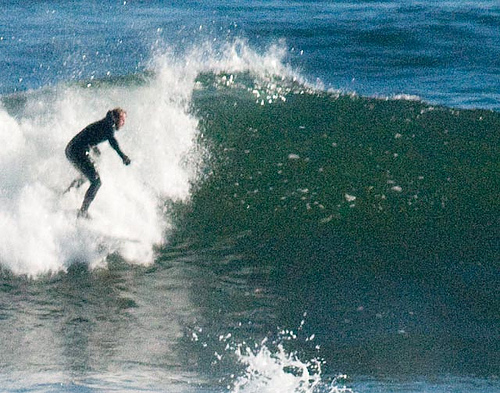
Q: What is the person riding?
A: A surfboard.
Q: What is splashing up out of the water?
A: Foam.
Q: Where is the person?
A: On the sea.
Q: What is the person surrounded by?
A: Foam splashing up out of the water.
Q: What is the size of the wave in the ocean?
A: Medium size.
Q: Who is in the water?
A: The man.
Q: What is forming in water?
A: Wave.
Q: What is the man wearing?
A: A black swimsuit.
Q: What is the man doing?
A: Surfing.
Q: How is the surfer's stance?
A: Bent down.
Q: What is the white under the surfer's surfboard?
A: A wave.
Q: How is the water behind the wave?
A: Calm.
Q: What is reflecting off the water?
A: The wave.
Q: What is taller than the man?
A: The wave.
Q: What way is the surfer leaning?
A: Forward.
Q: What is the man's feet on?
A: A surfboard.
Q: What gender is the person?
A: Male.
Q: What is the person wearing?
A: Wetsuit.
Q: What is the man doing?
A: Surfing.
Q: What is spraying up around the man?
A: Water.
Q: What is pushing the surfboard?
A: Wave.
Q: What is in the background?
A: Water.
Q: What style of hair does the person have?
A: Long.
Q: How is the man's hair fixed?
A: Ponytail.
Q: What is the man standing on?
A: Surfboard.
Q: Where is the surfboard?
A: In the water.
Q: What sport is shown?
A: Surfing.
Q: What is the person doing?
A: Surfing.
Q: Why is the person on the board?
A: To surf.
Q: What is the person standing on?
A: Surfboard.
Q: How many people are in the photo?
A: One.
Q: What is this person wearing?
A: A diving suit.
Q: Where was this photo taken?
A: In the ocean.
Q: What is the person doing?
A: Surfing.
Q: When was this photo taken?
A: Daytime.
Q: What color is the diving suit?
A: Black.